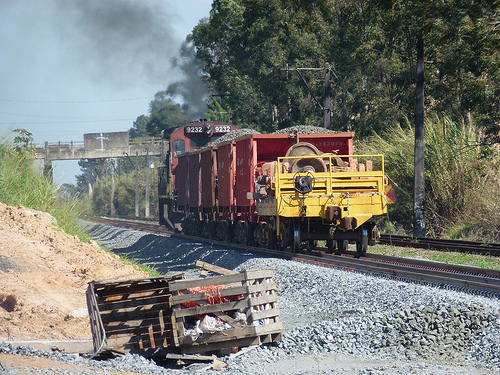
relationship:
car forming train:
[157, 118, 396, 253] [146, 110, 407, 266]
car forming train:
[174, 148, 189, 232] [146, 110, 407, 266]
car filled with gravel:
[157, 118, 396, 253] [267, 124, 341, 132]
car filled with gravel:
[157, 118, 396, 253] [210, 124, 260, 142]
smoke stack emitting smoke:
[198, 115, 208, 122] [0, 0, 210, 120]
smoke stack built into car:
[198, 115, 208, 122] [157, 118, 396, 253]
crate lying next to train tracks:
[167, 270, 284, 361] [82, 211, 498, 298]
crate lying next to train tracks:
[84, 272, 184, 358] [82, 211, 498, 298]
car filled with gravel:
[157, 118, 396, 253] [264, 122, 345, 132]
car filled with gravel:
[157, 118, 396, 253] [200, 127, 262, 147]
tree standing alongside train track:
[375, 0, 483, 235] [75, 210, 484, 298]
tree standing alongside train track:
[310, 4, 394, 134] [75, 210, 484, 298]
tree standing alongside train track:
[222, 0, 346, 127] [75, 210, 484, 298]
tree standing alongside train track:
[187, 0, 243, 75] [93, 210, 484, 255]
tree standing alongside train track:
[147, 95, 191, 135] [93, 210, 484, 255]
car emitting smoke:
[157, 118, 396, 253] [54, 1, 207, 124]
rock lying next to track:
[342, 305, 362, 313] [69, 210, 485, 298]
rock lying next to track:
[460, 317, 465, 324] [69, 210, 485, 298]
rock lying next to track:
[373, 320, 385, 327] [69, 210, 485, 298]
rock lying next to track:
[325, 332, 334, 341] [90, 211, 485, 257]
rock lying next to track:
[396, 282, 406, 287] [90, 211, 485, 257]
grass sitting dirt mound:
[2, 127, 163, 273] [1, 202, 157, 347]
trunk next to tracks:
[398, 42, 433, 239] [358, 231, 498, 296]